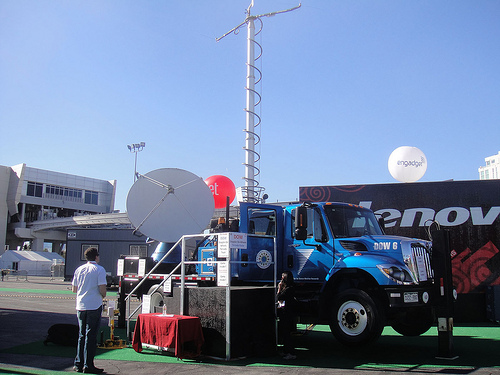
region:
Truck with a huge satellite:
[198, 2, 448, 348]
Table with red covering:
[127, 306, 207, 366]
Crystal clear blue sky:
[0, 0, 492, 170]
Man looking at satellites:
[60, 240, 105, 370]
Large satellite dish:
[121, 166, 217, 271]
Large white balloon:
[380, 142, 425, 182]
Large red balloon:
[202, 170, 240, 210]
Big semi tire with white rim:
[326, 282, 382, 348]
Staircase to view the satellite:
[129, 229, 271, 365]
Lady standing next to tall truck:
[271, 267, 306, 364]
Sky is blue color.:
[64, 33, 174, 123]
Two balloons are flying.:
[190, 131, 447, 231]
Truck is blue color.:
[199, 179, 439, 345]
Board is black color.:
[299, 169, 499, 308]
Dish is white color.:
[126, 148, 225, 273]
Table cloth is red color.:
[113, 299, 213, 368]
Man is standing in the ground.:
[65, 246, 120, 366]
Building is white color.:
[8, 152, 131, 242]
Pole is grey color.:
[229, 17, 281, 192]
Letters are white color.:
[335, 194, 497, 259]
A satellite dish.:
[120, 162, 215, 254]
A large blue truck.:
[141, 165, 464, 342]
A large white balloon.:
[378, 138, 435, 189]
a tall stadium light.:
[127, 129, 152, 179]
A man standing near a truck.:
[58, 238, 117, 374]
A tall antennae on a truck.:
[210, 0, 308, 216]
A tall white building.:
[0, 158, 131, 282]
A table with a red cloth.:
[126, 308, 221, 374]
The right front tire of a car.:
[321, 278, 384, 359]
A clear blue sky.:
[3, 0, 498, 210]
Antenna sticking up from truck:
[213, 3, 308, 203]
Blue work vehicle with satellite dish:
[122, 165, 444, 341]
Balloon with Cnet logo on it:
[202, 173, 240, 212]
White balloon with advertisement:
[386, 144, 428, 184]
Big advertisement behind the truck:
[297, 180, 499, 320]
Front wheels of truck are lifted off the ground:
[323, 218, 467, 365]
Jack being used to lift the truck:
[420, 217, 472, 363]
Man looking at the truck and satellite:
[70, 166, 447, 373]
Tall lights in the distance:
[125, 138, 148, 180]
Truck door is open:
[236, 198, 286, 288]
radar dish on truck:
[121, 150, 220, 267]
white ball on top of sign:
[383, 143, 433, 183]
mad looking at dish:
[68, 238, 115, 373]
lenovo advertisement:
[298, 186, 498, 330]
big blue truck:
[117, 188, 455, 355]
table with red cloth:
[126, 305, 206, 359]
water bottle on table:
[156, 300, 174, 317]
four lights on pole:
[121, 138, 152, 180]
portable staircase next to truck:
[123, 222, 285, 362]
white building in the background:
[0, 157, 122, 274]